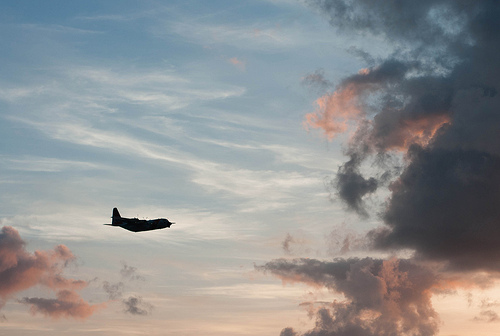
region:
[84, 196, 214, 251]
air plane in the sky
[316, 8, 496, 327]
clouds in the sky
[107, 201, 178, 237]
the plane has a dark color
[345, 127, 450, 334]
the clouds are fluffy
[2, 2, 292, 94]
the sky is blue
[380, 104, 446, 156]
the sun shines through the clouds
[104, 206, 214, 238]
the plane is flying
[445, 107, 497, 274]
the clouds are dard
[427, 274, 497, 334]
pink hue under the clouds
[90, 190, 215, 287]
the plane is high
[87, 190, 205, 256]
the plane is flying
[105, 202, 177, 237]
dark plane in evening sky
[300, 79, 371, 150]
pink hue of clouds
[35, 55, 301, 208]
white stratus cloud in evening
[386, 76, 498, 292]
dark thunder storm cloud filled with rain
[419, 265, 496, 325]
sun shining through clouds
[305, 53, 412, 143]
cloud in the shape of a tadpole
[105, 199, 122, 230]
airplane's tail in the rear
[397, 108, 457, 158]
orange hue in break in clouds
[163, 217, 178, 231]
airplane's left wing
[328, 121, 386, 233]
cloud in the shape of a snake's head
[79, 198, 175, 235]
Fighter jet at night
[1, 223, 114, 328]
Orange sunset at night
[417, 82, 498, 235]
Dark storm clouds in the sky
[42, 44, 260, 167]
White wispy clouds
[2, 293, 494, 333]
sunset on the horizon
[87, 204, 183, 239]
Military fighter jet in sky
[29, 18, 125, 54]
Clear blue sky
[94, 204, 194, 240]
Jet flying above the clouds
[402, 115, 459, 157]
sunlight peaking out of cloud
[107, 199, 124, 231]
Tail of fighter jet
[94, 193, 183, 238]
plane is flying through sky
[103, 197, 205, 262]
plane is flying through sky